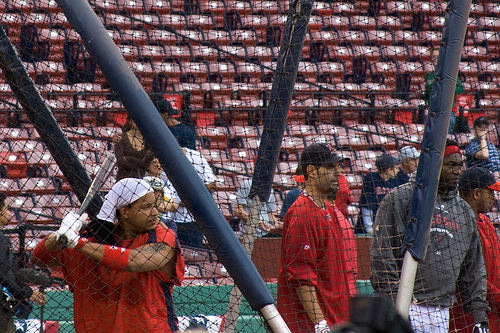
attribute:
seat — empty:
[379, 40, 411, 59]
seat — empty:
[321, 37, 355, 59]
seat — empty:
[293, 55, 320, 78]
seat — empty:
[202, 54, 237, 81]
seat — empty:
[0, 147, 30, 177]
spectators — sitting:
[357, 152, 404, 236]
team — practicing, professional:
[22, 153, 497, 331]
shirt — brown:
[112, 132, 155, 179]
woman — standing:
[111, 107, 153, 177]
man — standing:
[276, 140, 359, 331]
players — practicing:
[454, 161, 499, 329]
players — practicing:
[374, 145, 486, 318]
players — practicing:
[277, 130, 363, 328]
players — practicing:
[23, 177, 208, 325]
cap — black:
[296, 141, 354, 173]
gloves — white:
[49, 208, 118, 279]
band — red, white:
[101, 245, 127, 270]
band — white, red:
[30, 235, 63, 262]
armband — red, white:
[101, 242, 131, 269]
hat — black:
[295, 124, 347, 172]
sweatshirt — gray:
[369, 175, 486, 312]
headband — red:
[445, 146, 458, 153]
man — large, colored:
[368, 132, 487, 321]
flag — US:
[179, 305, 226, 327]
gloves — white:
[48, 211, 94, 248]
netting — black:
[1, 0, 498, 330]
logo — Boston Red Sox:
[429, 214, 461, 256]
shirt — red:
[275, 196, 380, 306]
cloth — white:
[92, 176, 153, 222]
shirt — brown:
[109, 130, 157, 186]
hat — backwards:
[150, 97, 182, 118]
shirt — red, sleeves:
[274, 184, 359, 324]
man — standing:
[374, 134, 488, 332]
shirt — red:
[31, 222, 189, 331]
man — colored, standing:
[33, 176, 183, 326]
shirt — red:
[450, 214, 499, 327]